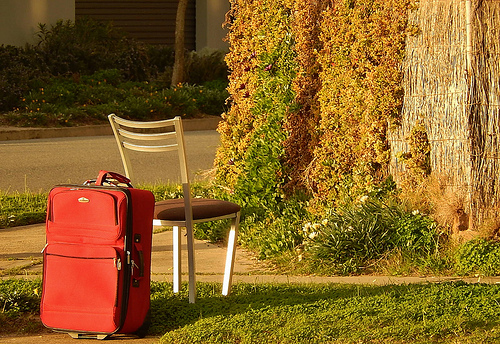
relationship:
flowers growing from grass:
[297, 205, 357, 253] [296, 194, 403, 264]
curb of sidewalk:
[1, 114, 224, 144] [3, 111, 228, 142]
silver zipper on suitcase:
[38, 242, 50, 256] [33, 173, 159, 333]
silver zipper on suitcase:
[110, 256, 122, 272] [33, 173, 159, 333]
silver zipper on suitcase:
[127, 260, 141, 278] [33, 173, 159, 333]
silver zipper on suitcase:
[120, 233, 132, 259] [33, 173, 159, 333]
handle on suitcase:
[75, 166, 138, 203] [34, 166, 164, 339]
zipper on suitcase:
[55, 184, 132, 334] [37, 168, 154, 341]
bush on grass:
[31, 17, 146, 77] [163, 286, 498, 342]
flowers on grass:
[354, 192, 384, 211] [252, 192, 433, 262]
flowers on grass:
[297, 205, 357, 253] [252, 192, 433, 262]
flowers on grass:
[399, 202, 430, 225] [252, 192, 433, 262]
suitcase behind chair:
[34, 166, 164, 339] [76, 92, 302, 314]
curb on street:
[4, 168, 240, 220] [2, 127, 223, 192]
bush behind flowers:
[31, 17, 146, 77] [154, 82, 199, 108]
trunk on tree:
[392, 0, 498, 245] [208, 7, 484, 241]